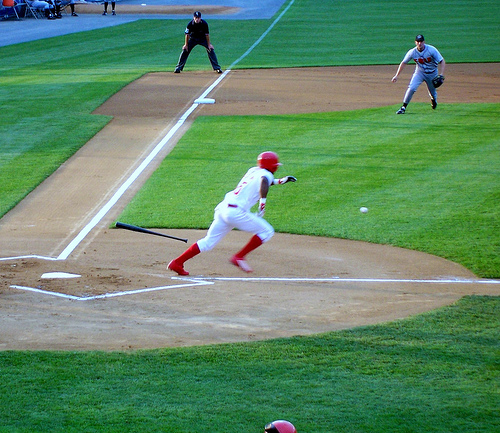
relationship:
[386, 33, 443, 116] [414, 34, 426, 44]
guy wearing hat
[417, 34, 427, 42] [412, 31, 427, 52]
hat on head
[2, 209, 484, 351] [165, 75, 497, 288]
section on field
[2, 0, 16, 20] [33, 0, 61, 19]
spectator to side spectator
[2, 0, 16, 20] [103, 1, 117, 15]
spectator to side spectator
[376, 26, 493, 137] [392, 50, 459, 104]
guy in uniform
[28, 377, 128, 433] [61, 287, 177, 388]
patch of grass in middle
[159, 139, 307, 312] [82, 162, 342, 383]
baseball player about to run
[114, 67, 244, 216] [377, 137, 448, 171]
lines on field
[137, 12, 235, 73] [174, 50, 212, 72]
umpire wearing a black shirt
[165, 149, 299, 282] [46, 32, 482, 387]
baseball player on a baseball field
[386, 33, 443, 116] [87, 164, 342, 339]
guy on a baseball field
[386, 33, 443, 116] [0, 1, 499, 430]
guy standing in a baseball field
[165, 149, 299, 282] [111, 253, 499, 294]
baseball player running down base path